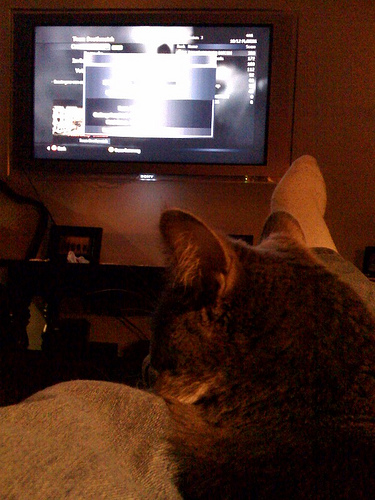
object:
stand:
[2, 232, 256, 383]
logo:
[138, 172, 157, 179]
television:
[8, 9, 297, 185]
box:
[83, 50, 216, 140]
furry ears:
[158, 208, 241, 307]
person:
[2, 156, 375, 499]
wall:
[0, 0, 375, 356]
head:
[140, 208, 366, 406]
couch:
[0, 379, 184, 499]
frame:
[50, 224, 103, 266]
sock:
[272, 154, 335, 250]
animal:
[141, 209, 375, 498]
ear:
[160, 209, 238, 306]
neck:
[204, 273, 351, 405]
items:
[27, 302, 46, 348]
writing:
[71, 35, 117, 43]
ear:
[258, 209, 307, 241]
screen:
[33, 28, 268, 164]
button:
[104, 144, 142, 154]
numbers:
[248, 98, 255, 106]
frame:
[15, 9, 298, 179]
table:
[0, 234, 253, 387]